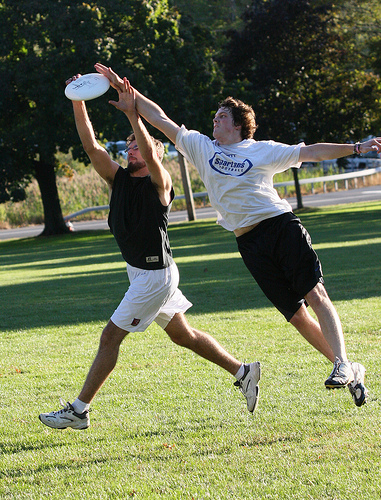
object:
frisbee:
[64, 72, 110, 101]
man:
[40, 62, 263, 434]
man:
[91, 62, 381, 407]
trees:
[213, 0, 379, 214]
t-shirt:
[106, 164, 173, 269]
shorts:
[110, 258, 193, 335]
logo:
[209, 151, 254, 176]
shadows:
[0, 197, 380, 264]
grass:
[0, 197, 381, 500]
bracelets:
[357, 141, 361, 154]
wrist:
[351, 143, 365, 155]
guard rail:
[64, 155, 380, 232]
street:
[2, 181, 379, 243]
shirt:
[170, 128, 305, 233]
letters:
[218, 165, 245, 172]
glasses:
[124, 146, 138, 152]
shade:
[6, 199, 379, 334]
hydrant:
[69, 226, 72, 232]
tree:
[2, 0, 180, 242]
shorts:
[232, 212, 327, 323]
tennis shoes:
[234, 361, 261, 411]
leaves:
[13, 17, 51, 73]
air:
[0, 4, 379, 500]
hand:
[94, 63, 118, 84]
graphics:
[215, 158, 246, 168]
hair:
[220, 96, 256, 140]